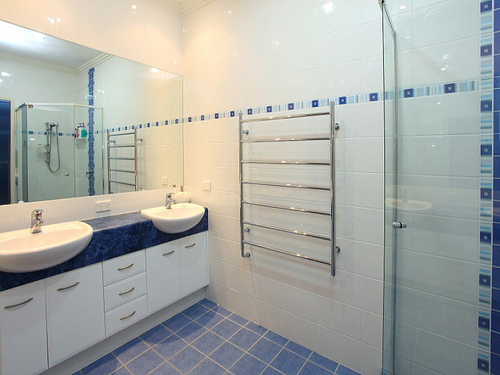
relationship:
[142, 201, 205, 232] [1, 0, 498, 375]
sink inside of bathroom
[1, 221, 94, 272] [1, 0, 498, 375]
sink inside of bathroom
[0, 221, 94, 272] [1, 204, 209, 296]
sink built into counter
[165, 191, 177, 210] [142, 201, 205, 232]
faucet on back of sink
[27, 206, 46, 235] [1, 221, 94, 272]
faucet on back of sink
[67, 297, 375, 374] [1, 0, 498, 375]
tile floor inside of bathroom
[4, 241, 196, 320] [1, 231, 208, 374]
handles on front of cabinets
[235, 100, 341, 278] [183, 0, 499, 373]
towel rack attached to wall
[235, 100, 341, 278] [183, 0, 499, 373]
towel rack mounted on wall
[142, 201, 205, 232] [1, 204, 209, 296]
sink built into counter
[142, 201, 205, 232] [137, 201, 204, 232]
sink has sink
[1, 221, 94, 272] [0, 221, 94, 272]
sink has sink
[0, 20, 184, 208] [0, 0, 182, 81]
mirror mounted on wall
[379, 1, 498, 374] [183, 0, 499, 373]
shower next to wall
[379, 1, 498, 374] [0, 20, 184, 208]
shower reflected in mirror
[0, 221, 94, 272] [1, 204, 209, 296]
sink on top of counter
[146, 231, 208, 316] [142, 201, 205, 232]
cabinet underneath sink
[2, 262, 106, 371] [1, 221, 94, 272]
cabinet underneath sink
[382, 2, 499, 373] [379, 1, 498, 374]
walls of shower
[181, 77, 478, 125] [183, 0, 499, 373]
accent in middle of wall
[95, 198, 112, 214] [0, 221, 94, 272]
outlet between sink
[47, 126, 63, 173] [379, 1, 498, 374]
hose inside of shower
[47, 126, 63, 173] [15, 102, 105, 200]
hose inside of shower